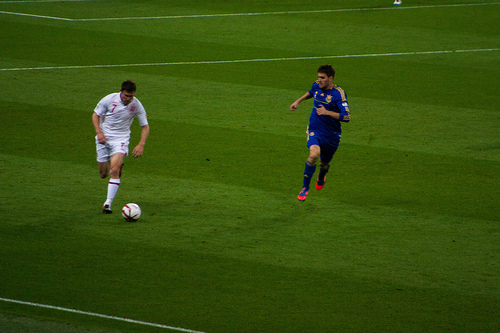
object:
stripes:
[122, 205, 137, 217]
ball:
[122, 203, 142, 222]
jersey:
[93, 92, 149, 141]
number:
[111, 104, 117, 113]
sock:
[103, 178, 120, 207]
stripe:
[109, 182, 120, 186]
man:
[91, 79, 149, 214]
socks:
[303, 160, 316, 188]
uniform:
[306, 80, 351, 163]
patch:
[206, 159, 210, 162]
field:
[0, 0, 499, 333]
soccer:
[22, 17, 443, 308]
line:
[0, 48, 500, 71]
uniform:
[94, 92, 149, 162]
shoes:
[297, 187, 310, 202]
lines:
[0, 2, 500, 22]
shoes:
[103, 204, 112, 214]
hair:
[121, 80, 136, 93]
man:
[290, 64, 351, 202]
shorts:
[95, 134, 131, 163]